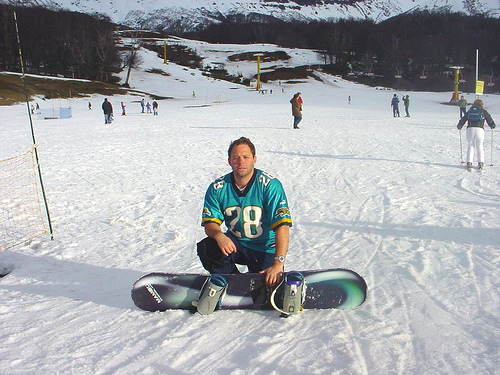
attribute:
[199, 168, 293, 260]
jersey — blue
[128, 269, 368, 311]
snowboard — standard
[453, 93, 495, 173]
lady — learning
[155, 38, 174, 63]
lift — ski resort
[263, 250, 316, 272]
watch — silver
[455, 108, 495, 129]
coat — black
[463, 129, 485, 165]
pants — white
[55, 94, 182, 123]
people — playing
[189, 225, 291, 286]
pants — white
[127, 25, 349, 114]
slope — ski slope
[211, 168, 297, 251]
jersey — green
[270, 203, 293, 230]
sleeve — yellow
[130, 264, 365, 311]
snowboard — black, white, green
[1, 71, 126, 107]
grass — brown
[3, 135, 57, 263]
net — yellow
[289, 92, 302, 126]
person — holding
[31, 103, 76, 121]
net — mesh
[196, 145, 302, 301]
man — kneeling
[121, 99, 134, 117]
child — standing